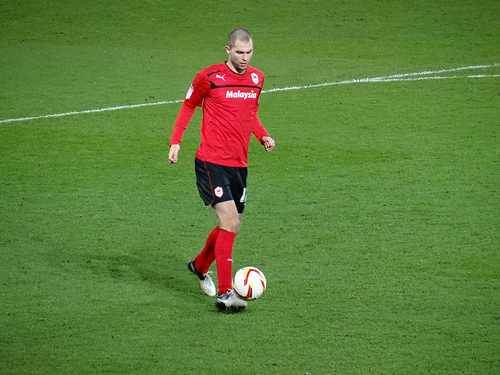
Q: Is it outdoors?
A: Yes, it is outdoors.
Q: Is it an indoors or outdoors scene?
A: It is outdoors.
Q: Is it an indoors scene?
A: No, it is outdoors.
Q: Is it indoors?
A: No, it is outdoors.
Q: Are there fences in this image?
A: No, there are no fences.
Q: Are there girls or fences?
A: No, there are no fences or girls.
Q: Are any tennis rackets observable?
A: No, there are no tennis rackets.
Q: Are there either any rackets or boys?
A: No, there are no rackets or boys.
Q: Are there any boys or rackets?
A: No, there are no rackets or boys.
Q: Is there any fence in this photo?
A: No, there are no fences.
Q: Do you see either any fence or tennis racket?
A: No, there are no fences or rackets.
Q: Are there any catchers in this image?
A: No, there are no catchers.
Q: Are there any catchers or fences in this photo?
A: No, there are no catchers or fences.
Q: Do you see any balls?
A: Yes, there is a ball.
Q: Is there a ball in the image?
A: Yes, there is a ball.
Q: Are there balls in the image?
A: Yes, there is a ball.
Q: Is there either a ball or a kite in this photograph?
A: Yes, there is a ball.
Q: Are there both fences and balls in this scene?
A: No, there is a ball but no fences.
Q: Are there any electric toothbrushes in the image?
A: No, there are no electric toothbrushes.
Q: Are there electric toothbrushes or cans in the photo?
A: No, there are no electric toothbrushes or cans.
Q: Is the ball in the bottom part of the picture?
A: Yes, the ball is in the bottom of the image.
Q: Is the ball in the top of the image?
A: No, the ball is in the bottom of the image.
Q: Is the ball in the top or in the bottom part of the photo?
A: The ball is in the bottom of the image.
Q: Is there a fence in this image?
A: No, there are no fences.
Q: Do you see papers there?
A: No, there are no papers.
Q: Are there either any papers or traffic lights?
A: No, there are no papers or traffic lights.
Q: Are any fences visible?
A: No, there are no fences.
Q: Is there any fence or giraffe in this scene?
A: No, there are no fences or giraffes.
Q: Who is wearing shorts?
A: The man is wearing shorts.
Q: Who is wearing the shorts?
A: The man is wearing shorts.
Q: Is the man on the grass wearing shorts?
A: Yes, the man is wearing shorts.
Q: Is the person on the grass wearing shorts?
A: Yes, the man is wearing shorts.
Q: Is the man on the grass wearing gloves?
A: No, the man is wearing shorts.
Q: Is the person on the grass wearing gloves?
A: No, the man is wearing shorts.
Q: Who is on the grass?
A: The man is on the grass.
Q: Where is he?
A: The man is on the grass.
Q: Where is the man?
A: The man is on the grass.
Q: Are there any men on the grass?
A: Yes, there is a man on the grass.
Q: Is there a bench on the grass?
A: No, there is a man on the grass.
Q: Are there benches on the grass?
A: No, there is a man on the grass.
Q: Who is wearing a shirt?
A: The man is wearing a shirt.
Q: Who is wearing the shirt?
A: The man is wearing a shirt.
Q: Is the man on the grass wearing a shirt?
A: Yes, the man is wearing a shirt.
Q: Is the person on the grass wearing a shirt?
A: Yes, the man is wearing a shirt.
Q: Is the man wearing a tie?
A: No, the man is wearing a shirt.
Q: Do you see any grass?
A: Yes, there is grass.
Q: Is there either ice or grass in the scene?
A: Yes, there is grass.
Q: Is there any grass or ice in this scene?
A: Yes, there is grass.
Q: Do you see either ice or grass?
A: Yes, there is grass.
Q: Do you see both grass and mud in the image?
A: No, there is grass but no mud.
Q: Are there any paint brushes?
A: No, there are no paint brushes.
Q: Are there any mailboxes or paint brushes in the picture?
A: No, there are no paint brushes or mailboxes.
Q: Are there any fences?
A: No, there are no fences.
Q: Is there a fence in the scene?
A: No, there are no fences.